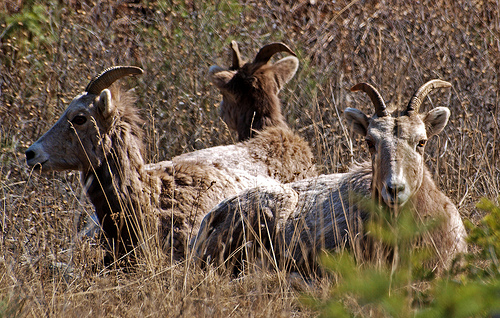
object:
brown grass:
[2, 1, 497, 316]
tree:
[99, 14, 237, 64]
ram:
[40, 80, 310, 245]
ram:
[186, 80, 470, 283]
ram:
[175, 38, 318, 175]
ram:
[22, 62, 317, 273]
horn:
[252, 41, 298, 67]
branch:
[324, 195, 500, 318]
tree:
[0, 0, 63, 67]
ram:
[8, 56, 215, 293]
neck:
[243, 103, 289, 132]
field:
[23, 10, 493, 307]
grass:
[7, 15, 467, 289]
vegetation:
[0, 271, 204, 317]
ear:
[425, 106, 452, 139]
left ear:
[205, 65, 237, 91]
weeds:
[57, 196, 311, 316]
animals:
[23, 64, 179, 280]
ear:
[343, 106, 370, 136]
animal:
[135, 39, 321, 269]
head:
[341, 79, 453, 211]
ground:
[10, 181, 489, 312]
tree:
[296, 200, 500, 317]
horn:
[349, 82, 389, 118]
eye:
[417, 139, 427, 147]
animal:
[197, 77, 467, 285]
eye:
[364, 138, 375, 149]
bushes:
[0, 2, 237, 147]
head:
[206, 40, 303, 141]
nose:
[386, 182, 405, 196]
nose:
[26, 147, 36, 160]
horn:
[85, 65, 146, 95]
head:
[23, 65, 146, 175]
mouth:
[390, 199, 403, 207]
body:
[140, 126, 316, 263]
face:
[365, 111, 428, 209]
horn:
[228, 40, 242, 68]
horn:
[405, 79, 452, 116]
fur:
[189, 166, 246, 198]